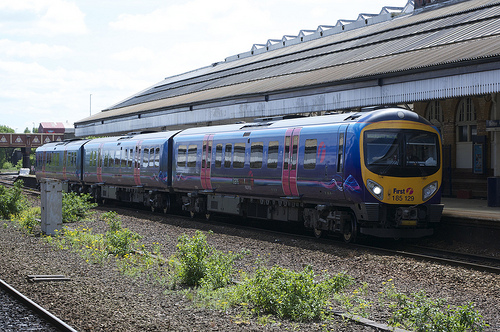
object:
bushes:
[231, 268, 323, 315]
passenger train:
[33, 104, 444, 242]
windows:
[304, 138, 318, 169]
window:
[284, 135, 299, 170]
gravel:
[75, 286, 177, 332]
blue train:
[35, 108, 445, 243]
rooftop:
[38, 122, 65, 133]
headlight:
[367, 180, 383, 200]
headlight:
[422, 181, 438, 200]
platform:
[445, 199, 499, 221]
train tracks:
[422, 227, 500, 275]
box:
[39, 177, 63, 235]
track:
[0, 172, 500, 332]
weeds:
[390, 301, 480, 328]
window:
[303, 138, 317, 169]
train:
[35, 108, 445, 244]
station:
[73, 0, 500, 222]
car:
[169, 106, 447, 243]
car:
[81, 129, 184, 213]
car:
[34, 137, 90, 192]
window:
[224, 144, 232, 169]